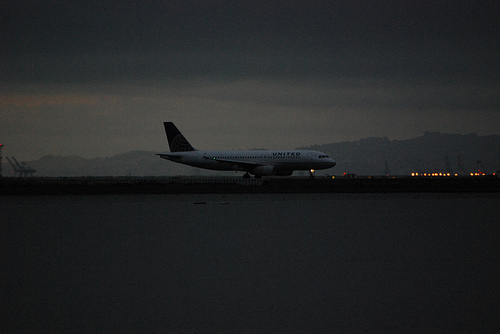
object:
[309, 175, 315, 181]
wheel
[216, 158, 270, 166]
wing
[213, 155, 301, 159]
windows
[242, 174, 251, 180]
wheels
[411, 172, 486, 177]
lights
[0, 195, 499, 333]
concrete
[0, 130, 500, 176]
hill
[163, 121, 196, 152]
tail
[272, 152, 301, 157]
name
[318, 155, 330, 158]
windshield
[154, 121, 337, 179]
airplane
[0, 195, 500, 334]
runway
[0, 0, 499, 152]
cloudy sky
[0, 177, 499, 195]
tarmac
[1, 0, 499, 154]
sky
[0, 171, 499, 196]
runway